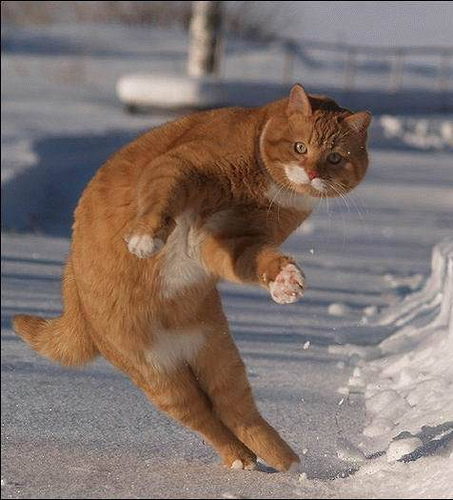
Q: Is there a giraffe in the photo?
A: No, there are no giraffes.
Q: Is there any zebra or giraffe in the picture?
A: No, there are no giraffes or zebras.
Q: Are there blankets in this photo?
A: No, there are no blankets.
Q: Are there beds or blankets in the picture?
A: No, there are no blankets or beds.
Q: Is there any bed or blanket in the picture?
A: No, there are no blankets or beds.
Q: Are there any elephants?
A: No, there are no elephants.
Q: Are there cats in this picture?
A: Yes, there is a cat.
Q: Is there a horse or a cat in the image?
A: Yes, there is a cat.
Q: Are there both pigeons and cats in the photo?
A: No, there is a cat but no pigeons.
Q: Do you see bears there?
A: No, there are no bears.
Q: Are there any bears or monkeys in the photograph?
A: No, there are no bears or monkeys.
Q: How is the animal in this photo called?
A: The animal is a cat.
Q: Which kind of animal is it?
A: The animal is a cat.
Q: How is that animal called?
A: This is a cat.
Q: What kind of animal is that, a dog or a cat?
A: This is a cat.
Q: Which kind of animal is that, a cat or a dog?
A: This is a cat.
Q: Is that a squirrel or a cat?
A: That is a cat.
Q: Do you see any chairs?
A: No, there are no chairs.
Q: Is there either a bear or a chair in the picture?
A: No, there are no chairs or bears.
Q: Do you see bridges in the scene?
A: Yes, there is a bridge.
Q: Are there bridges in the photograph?
A: Yes, there is a bridge.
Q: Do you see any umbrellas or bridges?
A: Yes, there is a bridge.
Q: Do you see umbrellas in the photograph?
A: No, there are no umbrellas.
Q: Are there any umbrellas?
A: No, there are no umbrellas.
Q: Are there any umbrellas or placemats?
A: No, there are no umbrellas or placemats.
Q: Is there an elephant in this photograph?
A: No, there are no elephants.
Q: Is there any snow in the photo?
A: Yes, there is snow.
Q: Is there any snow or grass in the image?
A: Yes, there is snow.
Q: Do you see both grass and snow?
A: No, there is snow but no grass.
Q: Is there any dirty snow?
A: Yes, there is dirty snow.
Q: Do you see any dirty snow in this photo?
A: Yes, there is dirty snow.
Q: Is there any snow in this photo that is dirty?
A: Yes, there is snow that is dirty.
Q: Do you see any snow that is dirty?
A: Yes, there is snow that is dirty.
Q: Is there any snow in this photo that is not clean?
A: Yes, there is dirty snow.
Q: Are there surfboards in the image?
A: No, there are no surfboards.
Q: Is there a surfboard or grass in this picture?
A: No, there are no surfboards or grass.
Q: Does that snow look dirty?
A: Yes, the snow is dirty.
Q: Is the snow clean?
A: No, the snow is dirty.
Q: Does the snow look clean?
A: No, the snow is dirty.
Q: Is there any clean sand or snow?
A: No, there is snow but it is dirty.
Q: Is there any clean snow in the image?
A: No, there is snow but it is dirty.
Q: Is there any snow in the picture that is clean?
A: No, there is snow but it is dirty.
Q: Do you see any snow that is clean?
A: No, there is snow but it is dirty.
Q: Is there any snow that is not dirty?
A: No, there is snow but it is dirty.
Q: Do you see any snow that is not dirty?
A: No, there is snow but it is dirty.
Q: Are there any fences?
A: Yes, there is a fence.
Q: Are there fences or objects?
A: Yes, there is a fence.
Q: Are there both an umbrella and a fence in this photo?
A: No, there is a fence but no umbrellas.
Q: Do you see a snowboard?
A: No, there are no snowboards.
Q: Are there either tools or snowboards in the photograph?
A: No, there are no snowboards or tools.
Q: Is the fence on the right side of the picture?
A: Yes, the fence is on the right of the image.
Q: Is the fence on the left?
A: No, the fence is on the right of the image.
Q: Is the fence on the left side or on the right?
A: The fence is on the right of the image.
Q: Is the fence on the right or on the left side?
A: The fence is on the right of the image.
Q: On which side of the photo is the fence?
A: The fence is on the right of the image.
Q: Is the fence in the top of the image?
A: Yes, the fence is in the top of the image.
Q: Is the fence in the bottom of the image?
A: No, the fence is in the top of the image.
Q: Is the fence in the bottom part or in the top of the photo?
A: The fence is in the top of the image.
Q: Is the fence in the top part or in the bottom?
A: The fence is in the top of the image.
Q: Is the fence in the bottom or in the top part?
A: The fence is in the top of the image.